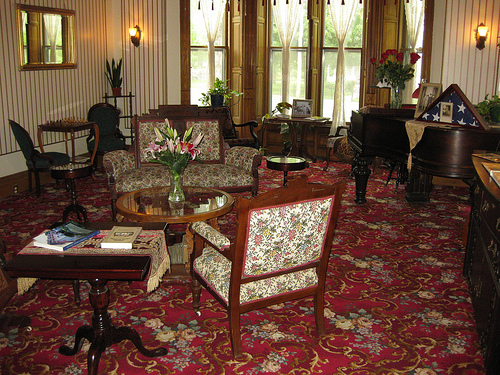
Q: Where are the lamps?
A: On the back wall.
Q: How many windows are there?
A: Four.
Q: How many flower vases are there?
A: Two.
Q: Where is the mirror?
A: On the left wall.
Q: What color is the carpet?
A: Red floral pattern.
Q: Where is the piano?
A: To the right.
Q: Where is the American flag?
A: On top of the piano.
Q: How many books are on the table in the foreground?
A: Two.